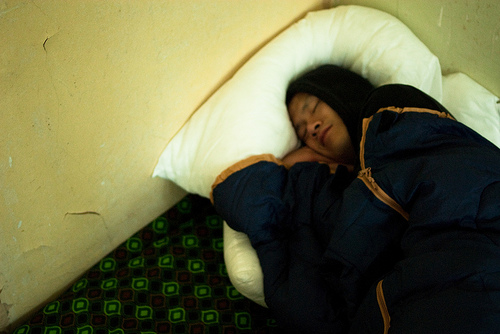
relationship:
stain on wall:
[7, 154, 15, 166] [0, 1, 329, 334]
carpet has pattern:
[0, 193, 277, 333] [153, 215, 168, 233]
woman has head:
[212, 66, 499, 334] [286, 62, 376, 161]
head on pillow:
[286, 62, 376, 161] [152, 6, 443, 200]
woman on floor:
[212, 66, 499, 334] [0, 193, 499, 333]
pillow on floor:
[152, 6, 443, 200] [0, 193, 499, 333]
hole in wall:
[65, 206, 105, 223] [0, 1, 329, 334]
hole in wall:
[42, 32, 56, 54] [0, 1, 329, 334]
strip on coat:
[210, 153, 279, 204] [212, 86, 499, 331]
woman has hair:
[212, 66, 499, 334] [285, 65, 376, 151]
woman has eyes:
[212, 66, 499, 334] [300, 102, 319, 139]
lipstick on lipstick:
[319, 124, 333, 145] [319, 124, 333, 145]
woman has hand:
[212, 66, 499, 334] [286, 146, 335, 167]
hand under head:
[286, 146, 335, 167] [286, 62, 376, 161]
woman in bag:
[212, 66, 499, 334] [210, 106, 500, 333]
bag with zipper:
[210, 106, 500, 333] [357, 167, 384, 197]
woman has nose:
[212, 66, 499, 334] [307, 119, 323, 137]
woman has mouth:
[212, 66, 499, 334] [319, 124, 334, 147]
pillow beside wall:
[152, 6, 443, 200] [0, 1, 329, 334]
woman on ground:
[212, 66, 499, 334] [2, 194, 500, 333]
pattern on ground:
[153, 215, 168, 233] [2, 194, 500, 333]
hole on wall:
[42, 32, 56, 54] [0, 1, 329, 334]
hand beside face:
[286, 146, 335, 167] [286, 93, 351, 159]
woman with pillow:
[212, 66, 499, 334] [152, 6, 443, 200]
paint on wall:
[34, 31, 114, 101] [0, 1, 329, 334]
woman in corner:
[212, 66, 499, 334] [311, 2, 368, 70]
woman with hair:
[212, 66, 499, 334] [285, 65, 376, 151]